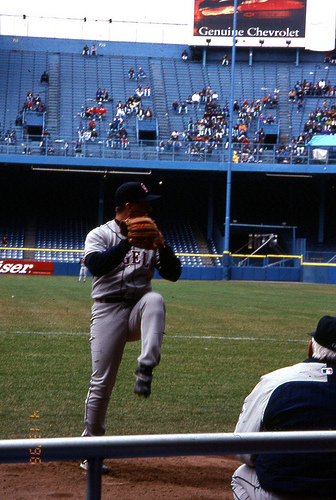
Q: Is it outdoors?
A: Yes, it is outdoors.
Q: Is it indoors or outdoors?
A: It is outdoors.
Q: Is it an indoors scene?
A: No, it is outdoors.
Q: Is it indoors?
A: No, it is outdoors.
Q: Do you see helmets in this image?
A: No, there are no helmets.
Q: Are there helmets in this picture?
A: No, there are no helmets.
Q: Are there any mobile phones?
A: No, there are no mobile phones.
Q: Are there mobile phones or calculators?
A: No, there are no mobile phones or calculators.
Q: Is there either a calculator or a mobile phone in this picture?
A: No, there are no cell phones or calculators.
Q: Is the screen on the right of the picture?
A: Yes, the screen is on the right of the image.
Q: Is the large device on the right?
A: Yes, the screen is on the right of the image.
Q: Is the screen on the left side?
A: No, the screen is on the right of the image.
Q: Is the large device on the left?
A: No, the screen is on the right of the image.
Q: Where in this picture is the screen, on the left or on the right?
A: The screen is on the right of the image.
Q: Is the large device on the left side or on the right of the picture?
A: The screen is on the right of the image.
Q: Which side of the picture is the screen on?
A: The screen is on the right of the image.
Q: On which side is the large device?
A: The screen is on the right of the image.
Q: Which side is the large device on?
A: The screen is on the right of the image.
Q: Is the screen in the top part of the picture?
A: Yes, the screen is in the top of the image.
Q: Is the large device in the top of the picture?
A: Yes, the screen is in the top of the image.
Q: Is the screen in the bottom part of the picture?
A: No, the screen is in the top of the image.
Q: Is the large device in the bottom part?
A: No, the screen is in the top of the image.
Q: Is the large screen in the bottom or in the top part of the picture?
A: The screen is in the top of the image.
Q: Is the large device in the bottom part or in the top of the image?
A: The screen is in the top of the image.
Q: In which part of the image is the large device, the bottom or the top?
A: The screen is in the top of the image.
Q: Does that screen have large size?
A: Yes, the screen is large.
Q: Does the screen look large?
A: Yes, the screen is large.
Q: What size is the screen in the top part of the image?
A: The screen is large.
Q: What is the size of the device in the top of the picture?
A: The screen is large.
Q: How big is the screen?
A: The screen is large.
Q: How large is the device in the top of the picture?
A: The screen is large.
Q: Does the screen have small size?
A: No, the screen is large.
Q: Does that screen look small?
A: No, the screen is large.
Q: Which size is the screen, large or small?
A: The screen is large.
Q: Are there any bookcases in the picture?
A: No, there are no bookcases.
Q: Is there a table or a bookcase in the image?
A: No, there are no bookcases or tables.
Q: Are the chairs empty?
A: Yes, the chairs are empty.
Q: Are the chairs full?
A: No, the chairs are empty.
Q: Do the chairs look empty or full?
A: The chairs are empty.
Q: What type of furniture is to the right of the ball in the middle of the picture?
A: The pieces of furniture are chairs.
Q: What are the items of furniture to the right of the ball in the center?
A: The pieces of furniture are chairs.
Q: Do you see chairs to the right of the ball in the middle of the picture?
A: Yes, there are chairs to the right of the ball.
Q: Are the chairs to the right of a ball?
A: Yes, the chairs are to the right of a ball.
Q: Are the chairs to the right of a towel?
A: No, the chairs are to the right of a ball.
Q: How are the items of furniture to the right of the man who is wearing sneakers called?
A: The pieces of furniture are chairs.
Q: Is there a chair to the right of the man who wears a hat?
A: Yes, there are chairs to the right of the man.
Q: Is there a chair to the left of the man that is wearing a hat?
A: No, the chairs are to the right of the man.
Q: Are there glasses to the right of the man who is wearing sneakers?
A: No, there are chairs to the right of the man.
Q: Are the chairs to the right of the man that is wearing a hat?
A: Yes, the chairs are to the right of the man.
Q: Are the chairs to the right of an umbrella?
A: No, the chairs are to the right of the man.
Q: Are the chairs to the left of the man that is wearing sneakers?
A: No, the chairs are to the right of the man.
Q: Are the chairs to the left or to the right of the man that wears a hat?
A: The chairs are to the right of the man.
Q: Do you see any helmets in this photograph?
A: No, there are no helmets.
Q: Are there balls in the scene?
A: Yes, there is a ball.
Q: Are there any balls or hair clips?
A: Yes, there is a ball.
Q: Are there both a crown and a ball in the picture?
A: No, there is a ball but no crowns.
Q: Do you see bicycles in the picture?
A: No, there are no bicycles.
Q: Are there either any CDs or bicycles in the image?
A: No, there are no bicycles or cds.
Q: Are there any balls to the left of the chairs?
A: Yes, there is a ball to the left of the chairs.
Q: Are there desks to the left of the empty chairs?
A: No, there is a ball to the left of the chairs.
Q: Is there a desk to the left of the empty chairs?
A: No, there is a ball to the left of the chairs.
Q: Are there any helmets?
A: No, there are no helmets.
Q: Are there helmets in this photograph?
A: No, there are no helmets.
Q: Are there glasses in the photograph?
A: No, there are no glasses.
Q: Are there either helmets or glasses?
A: No, there are no glasses or helmets.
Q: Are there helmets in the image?
A: No, there are no helmets.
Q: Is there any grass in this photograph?
A: Yes, there is grass.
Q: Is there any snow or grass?
A: Yes, there is grass.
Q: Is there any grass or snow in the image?
A: Yes, there is grass.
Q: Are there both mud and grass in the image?
A: No, there is grass but no mud.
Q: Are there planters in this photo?
A: No, there are no planters.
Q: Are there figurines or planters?
A: No, there are no planters or figurines.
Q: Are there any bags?
A: No, there are no bags.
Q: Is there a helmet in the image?
A: No, there are no helmets.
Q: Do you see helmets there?
A: No, there are no helmets.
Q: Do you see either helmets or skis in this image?
A: No, there are no helmets or skis.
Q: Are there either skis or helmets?
A: No, there are no helmets or skis.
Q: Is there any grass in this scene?
A: Yes, there is grass.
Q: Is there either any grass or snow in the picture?
A: Yes, there is grass.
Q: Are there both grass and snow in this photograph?
A: No, there is grass but no snow.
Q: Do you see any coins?
A: No, there are no coins.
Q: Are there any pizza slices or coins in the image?
A: No, there are no coins or pizza slices.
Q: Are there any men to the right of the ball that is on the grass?
A: Yes, there is a man to the right of the ball.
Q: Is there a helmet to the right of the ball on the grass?
A: No, there is a man to the right of the ball.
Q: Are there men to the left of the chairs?
A: Yes, there is a man to the left of the chairs.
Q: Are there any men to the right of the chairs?
A: No, the man is to the left of the chairs.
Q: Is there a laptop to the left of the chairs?
A: No, there is a man to the left of the chairs.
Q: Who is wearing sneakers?
A: The man is wearing sneakers.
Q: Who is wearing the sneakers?
A: The man is wearing sneakers.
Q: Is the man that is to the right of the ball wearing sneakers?
A: Yes, the man is wearing sneakers.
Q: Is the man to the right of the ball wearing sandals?
A: No, the man is wearing sneakers.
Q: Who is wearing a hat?
A: The man is wearing a hat.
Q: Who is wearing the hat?
A: The man is wearing a hat.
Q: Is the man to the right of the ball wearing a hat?
A: Yes, the man is wearing a hat.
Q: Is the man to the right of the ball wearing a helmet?
A: No, the man is wearing a hat.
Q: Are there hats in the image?
A: Yes, there is a hat.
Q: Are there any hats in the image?
A: Yes, there is a hat.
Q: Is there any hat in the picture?
A: Yes, there is a hat.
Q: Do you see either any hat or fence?
A: Yes, there is a hat.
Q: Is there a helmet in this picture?
A: No, there are no helmets.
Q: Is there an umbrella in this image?
A: No, there are no umbrellas.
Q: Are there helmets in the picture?
A: No, there are no helmets.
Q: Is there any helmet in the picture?
A: No, there are no helmets.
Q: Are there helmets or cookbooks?
A: No, there are no helmets or cookbooks.